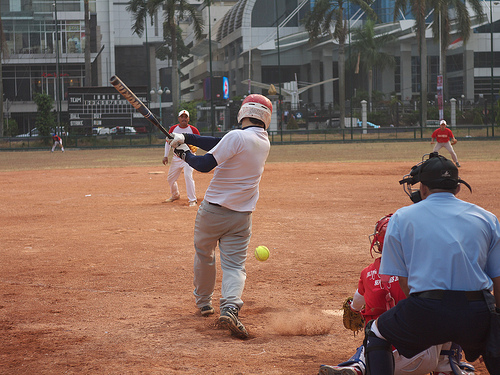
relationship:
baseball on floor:
[240, 233, 299, 283] [0, 126, 500, 375]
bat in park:
[108, 74, 175, 139] [13, 100, 350, 340]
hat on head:
[413, 151, 463, 191] [401, 150, 468, 195]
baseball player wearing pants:
[164, 93, 271, 340] [190, 199, 253, 309]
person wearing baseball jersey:
[430, 121, 460, 167] [431, 128, 454, 143]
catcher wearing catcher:
[341, 213, 476, 373] [321, 213, 475, 375]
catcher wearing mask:
[341, 213, 476, 373] [369, 214, 394, 256]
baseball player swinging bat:
[168, 91, 270, 338] [109, 76, 178, 145]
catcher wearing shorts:
[360, 152, 500, 375] [376, 290, 498, 364]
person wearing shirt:
[430, 121, 460, 167] [430, 127, 452, 142]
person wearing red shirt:
[47, 132, 67, 153] [52, 136, 63, 141]